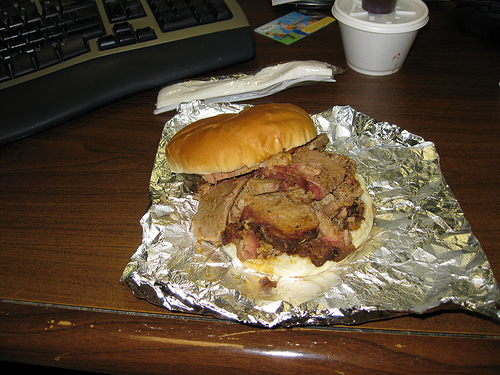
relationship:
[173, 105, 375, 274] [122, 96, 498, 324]
sandwhich in foil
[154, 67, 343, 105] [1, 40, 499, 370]
fork on table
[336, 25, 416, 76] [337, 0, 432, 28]
container with lid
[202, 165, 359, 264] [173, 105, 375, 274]
beef in sandwhich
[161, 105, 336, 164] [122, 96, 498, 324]
bun on foil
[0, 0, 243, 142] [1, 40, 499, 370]
keyboard on table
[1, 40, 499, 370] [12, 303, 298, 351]
table has scratches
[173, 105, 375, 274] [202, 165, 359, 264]
sandwhich has beef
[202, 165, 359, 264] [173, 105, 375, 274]
beef on sandwhich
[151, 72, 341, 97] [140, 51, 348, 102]
napkin with plasticware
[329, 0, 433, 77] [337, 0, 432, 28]
container with lid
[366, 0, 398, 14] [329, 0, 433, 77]
sauce on container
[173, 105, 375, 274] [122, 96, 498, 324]
sandwhich on foil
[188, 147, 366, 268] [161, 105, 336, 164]
beef on bun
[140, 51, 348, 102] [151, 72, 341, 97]
plasticware on napkin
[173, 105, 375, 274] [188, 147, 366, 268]
sandwhich with beef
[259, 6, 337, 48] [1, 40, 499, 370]
card on table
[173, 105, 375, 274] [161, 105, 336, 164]
sandwhich has bun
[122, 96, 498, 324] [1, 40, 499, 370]
foil on table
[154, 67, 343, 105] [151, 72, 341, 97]
fork and napkin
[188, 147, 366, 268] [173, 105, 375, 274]
beef on sandwhich